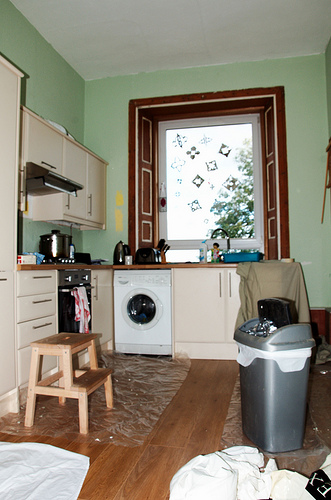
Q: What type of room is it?
A: It is a kitchen.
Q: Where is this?
A: This is at the kitchen.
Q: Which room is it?
A: It is a kitchen.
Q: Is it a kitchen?
A: Yes, it is a kitchen.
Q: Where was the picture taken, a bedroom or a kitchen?
A: It was taken at a kitchen.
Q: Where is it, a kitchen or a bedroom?
A: It is a kitchen.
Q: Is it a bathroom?
A: No, it is a kitchen.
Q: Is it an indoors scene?
A: Yes, it is indoors.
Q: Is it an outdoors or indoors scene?
A: It is indoors.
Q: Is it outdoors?
A: No, it is indoors.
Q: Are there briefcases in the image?
A: No, there are no briefcases.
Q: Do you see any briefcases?
A: No, there are no briefcases.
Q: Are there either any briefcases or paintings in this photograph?
A: No, there are no briefcases or paintings.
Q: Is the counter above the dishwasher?
A: Yes, the counter is above the dishwasher.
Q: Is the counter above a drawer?
A: No, the counter is above the dishwasher.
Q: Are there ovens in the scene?
A: Yes, there is an oven.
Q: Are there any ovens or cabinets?
A: Yes, there is an oven.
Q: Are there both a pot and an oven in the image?
A: Yes, there are both an oven and a pot.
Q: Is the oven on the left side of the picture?
A: Yes, the oven is on the left of the image.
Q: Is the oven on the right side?
A: No, the oven is on the left of the image.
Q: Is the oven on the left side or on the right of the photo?
A: The oven is on the left of the image.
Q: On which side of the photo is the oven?
A: The oven is on the left of the image.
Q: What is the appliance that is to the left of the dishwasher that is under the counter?
A: The appliance is an oven.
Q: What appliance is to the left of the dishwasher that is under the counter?
A: The appliance is an oven.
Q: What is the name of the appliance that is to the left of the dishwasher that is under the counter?
A: The appliance is an oven.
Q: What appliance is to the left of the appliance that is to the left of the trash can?
A: The appliance is an oven.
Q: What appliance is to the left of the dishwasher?
A: The appliance is an oven.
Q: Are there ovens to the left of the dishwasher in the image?
A: Yes, there is an oven to the left of the dishwasher.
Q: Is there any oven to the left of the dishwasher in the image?
A: Yes, there is an oven to the left of the dishwasher.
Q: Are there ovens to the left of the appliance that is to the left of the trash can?
A: Yes, there is an oven to the left of the dishwasher.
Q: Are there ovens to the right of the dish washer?
A: No, the oven is to the left of the dish washer.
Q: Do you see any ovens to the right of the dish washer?
A: No, the oven is to the left of the dish washer.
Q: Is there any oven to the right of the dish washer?
A: No, the oven is to the left of the dish washer.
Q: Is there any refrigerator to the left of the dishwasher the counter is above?
A: No, there is an oven to the left of the dish washer.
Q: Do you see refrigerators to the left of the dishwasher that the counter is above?
A: No, there is an oven to the left of the dish washer.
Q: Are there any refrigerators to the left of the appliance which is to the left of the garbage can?
A: No, there is an oven to the left of the dish washer.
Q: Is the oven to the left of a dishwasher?
A: Yes, the oven is to the left of a dishwasher.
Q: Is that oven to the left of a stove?
A: No, the oven is to the left of a dishwasher.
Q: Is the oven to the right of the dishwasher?
A: No, the oven is to the left of the dishwasher.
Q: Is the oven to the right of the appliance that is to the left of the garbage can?
A: No, the oven is to the left of the dishwasher.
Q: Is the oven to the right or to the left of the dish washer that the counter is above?
A: The oven is to the left of the dishwasher.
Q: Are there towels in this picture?
A: Yes, there is a towel.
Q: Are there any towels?
A: Yes, there is a towel.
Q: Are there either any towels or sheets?
A: Yes, there is a towel.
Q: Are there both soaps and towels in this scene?
A: No, there is a towel but no soaps.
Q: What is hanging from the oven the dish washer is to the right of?
A: The towel is hanging from the oven.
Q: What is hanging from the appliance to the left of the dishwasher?
A: The towel is hanging from the oven.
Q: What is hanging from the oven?
A: The towel is hanging from the oven.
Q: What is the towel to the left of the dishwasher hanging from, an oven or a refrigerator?
A: The towel is hanging from an oven.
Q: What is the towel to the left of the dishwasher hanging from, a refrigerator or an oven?
A: The towel is hanging from an oven.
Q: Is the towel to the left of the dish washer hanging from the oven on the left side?
A: Yes, the towel is hanging from the oven.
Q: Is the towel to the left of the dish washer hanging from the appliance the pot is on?
A: Yes, the towel is hanging from the oven.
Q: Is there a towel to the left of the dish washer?
A: Yes, there is a towel to the left of the dish washer.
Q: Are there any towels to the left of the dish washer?
A: Yes, there is a towel to the left of the dish washer.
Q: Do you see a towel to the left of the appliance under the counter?
A: Yes, there is a towel to the left of the dish washer.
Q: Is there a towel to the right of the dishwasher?
A: No, the towel is to the left of the dishwasher.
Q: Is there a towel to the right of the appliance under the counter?
A: No, the towel is to the left of the dishwasher.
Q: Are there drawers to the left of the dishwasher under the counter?
A: No, there is a towel to the left of the dish washer.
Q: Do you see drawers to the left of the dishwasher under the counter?
A: No, there is a towel to the left of the dish washer.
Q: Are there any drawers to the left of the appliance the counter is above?
A: No, there is a towel to the left of the dish washer.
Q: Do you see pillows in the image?
A: No, there are no pillows.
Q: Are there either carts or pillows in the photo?
A: No, there are no pillows or carts.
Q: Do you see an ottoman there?
A: No, there are no ottomen.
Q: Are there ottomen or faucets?
A: No, there are no ottomen or faucets.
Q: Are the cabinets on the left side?
A: Yes, the cabinets are on the left of the image.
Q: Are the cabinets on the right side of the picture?
A: No, the cabinets are on the left of the image.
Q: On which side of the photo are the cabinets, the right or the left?
A: The cabinets are on the left of the image.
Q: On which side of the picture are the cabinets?
A: The cabinets are on the left of the image.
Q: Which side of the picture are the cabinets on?
A: The cabinets are on the left of the image.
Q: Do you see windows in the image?
A: Yes, there is a window.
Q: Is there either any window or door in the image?
A: Yes, there is a window.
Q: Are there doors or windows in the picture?
A: Yes, there is a window.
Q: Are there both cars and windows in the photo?
A: No, there is a window but no cars.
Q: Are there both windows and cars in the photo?
A: No, there is a window but no cars.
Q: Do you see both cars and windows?
A: No, there is a window but no cars.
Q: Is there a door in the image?
A: No, there are no doors.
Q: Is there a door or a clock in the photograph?
A: No, there are no doors or clocks.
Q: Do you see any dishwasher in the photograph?
A: Yes, there is a dishwasher.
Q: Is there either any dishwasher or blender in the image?
A: Yes, there is a dishwasher.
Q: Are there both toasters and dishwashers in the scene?
A: Yes, there are both a dishwasher and a toaster.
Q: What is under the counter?
A: The dishwasher is under the counter.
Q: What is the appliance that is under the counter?
A: The appliance is a dishwasher.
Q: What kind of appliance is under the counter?
A: The appliance is a dishwasher.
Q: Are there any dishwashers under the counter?
A: Yes, there is a dishwasher under the counter.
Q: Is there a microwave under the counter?
A: No, there is a dishwasher under the counter.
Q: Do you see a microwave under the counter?
A: No, there is a dishwasher under the counter.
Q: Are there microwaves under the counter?
A: No, there is a dishwasher under the counter.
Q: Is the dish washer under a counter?
A: Yes, the dish washer is under a counter.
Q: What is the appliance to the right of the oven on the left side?
A: The appliance is a dishwasher.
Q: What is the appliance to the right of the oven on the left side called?
A: The appliance is a dishwasher.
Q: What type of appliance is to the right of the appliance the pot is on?
A: The appliance is a dishwasher.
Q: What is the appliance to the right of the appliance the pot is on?
A: The appliance is a dishwasher.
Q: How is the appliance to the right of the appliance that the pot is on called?
A: The appliance is a dishwasher.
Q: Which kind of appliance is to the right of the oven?
A: The appliance is a dishwasher.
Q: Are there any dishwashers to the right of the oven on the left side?
A: Yes, there is a dishwasher to the right of the oven.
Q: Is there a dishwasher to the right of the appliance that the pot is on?
A: Yes, there is a dishwasher to the right of the oven.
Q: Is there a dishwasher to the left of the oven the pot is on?
A: No, the dishwasher is to the right of the oven.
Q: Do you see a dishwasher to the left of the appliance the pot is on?
A: No, the dishwasher is to the right of the oven.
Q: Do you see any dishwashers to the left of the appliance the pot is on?
A: No, the dishwasher is to the right of the oven.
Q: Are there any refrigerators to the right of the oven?
A: No, there is a dishwasher to the right of the oven.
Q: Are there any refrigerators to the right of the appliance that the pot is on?
A: No, there is a dishwasher to the right of the oven.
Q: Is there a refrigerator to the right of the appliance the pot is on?
A: No, there is a dishwasher to the right of the oven.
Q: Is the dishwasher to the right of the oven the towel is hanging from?
A: Yes, the dishwasher is to the right of the oven.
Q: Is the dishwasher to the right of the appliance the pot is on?
A: Yes, the dishwasher is to the right of the oven.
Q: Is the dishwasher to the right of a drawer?
A: No, the dishwasher is to the right of the oven.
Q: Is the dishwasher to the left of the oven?
A: No, the dishwasher is to the right of the oven.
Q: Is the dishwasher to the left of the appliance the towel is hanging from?
A: No, the dishwasher is to the right of the oven.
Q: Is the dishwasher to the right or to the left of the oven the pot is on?
A: The dishwasher is to the right of the oven.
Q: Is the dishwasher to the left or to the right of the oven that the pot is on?
A: The dishwasher is to the right of the oven.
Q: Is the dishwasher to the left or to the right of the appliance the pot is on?
A: The dishwasher is to the right of the oven.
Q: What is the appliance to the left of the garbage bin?
A: The appliance is a dishwasher.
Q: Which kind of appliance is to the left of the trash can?
A: The appliance is a dishwasher.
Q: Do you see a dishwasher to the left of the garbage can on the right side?
A: Yes, there is a dishwasher to the left of the garbage bin.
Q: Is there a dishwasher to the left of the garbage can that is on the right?
A: Yes, there is a dishwasher to the left of the garbage bin.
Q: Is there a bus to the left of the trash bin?
A: No, there is a dishwasher to the left of the trash bin.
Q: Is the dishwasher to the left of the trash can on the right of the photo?
A: Yes, the dishwasher is to the left of the trashcan.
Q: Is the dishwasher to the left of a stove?
A: No, the dishwasher is to the left of the trashcan.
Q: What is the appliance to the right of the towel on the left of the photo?
A: The appliance is a dishwasher.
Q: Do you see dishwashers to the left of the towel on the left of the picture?
A: No, the dishwasher is to the right of the towel.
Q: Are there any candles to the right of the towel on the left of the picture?
A: No, there is a dishwasher to the right of the towel.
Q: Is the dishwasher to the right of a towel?
A: Yes, the dishwasher is to the right of a towel.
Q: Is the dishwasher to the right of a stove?
A: No, the dishwasher is to the right of a towel.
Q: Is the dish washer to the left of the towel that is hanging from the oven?
A: No, the dish washer is to the right of the towel.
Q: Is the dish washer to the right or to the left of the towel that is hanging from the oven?
A: The dish washer is to the right of the towel.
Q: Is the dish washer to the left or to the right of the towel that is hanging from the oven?
A: The dish washer is to the right of the towel.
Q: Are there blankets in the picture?
A: Yes, there is a blanket.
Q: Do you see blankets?
A: Yes, there is a blanket.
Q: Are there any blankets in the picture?
A: Yes, there is a blanket.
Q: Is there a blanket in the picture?
A: Yes, there is a blanket.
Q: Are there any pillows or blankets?
A: Yes, there is a blanket.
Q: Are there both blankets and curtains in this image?
A: No, there is a blanket but no curtains.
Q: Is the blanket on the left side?
A: Yes, the blanket is on the left of the image.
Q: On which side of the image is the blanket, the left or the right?
A: The blanket is on the left of the image.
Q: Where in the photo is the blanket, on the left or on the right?
A: The blanket is on the left of the image.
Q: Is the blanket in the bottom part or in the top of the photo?
A: The blanket is in the bottom of the image.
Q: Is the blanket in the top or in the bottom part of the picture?
A: The blanket is in the bottom of the image.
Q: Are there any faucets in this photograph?
A: No, there are no faucets.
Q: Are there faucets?
A: No, there are no faucets.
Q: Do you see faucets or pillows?
A: No, there are no faucets or pillows.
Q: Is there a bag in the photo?
A: Yes, there is a bag.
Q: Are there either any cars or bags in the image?
A: Yes, there is a bag.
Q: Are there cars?
A: No, there are no cars.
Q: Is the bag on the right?
A: Yes, the bag is on the right of the image.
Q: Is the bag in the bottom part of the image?
A: Yes, the bag is in the bottom of the image.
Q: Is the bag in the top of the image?
A: No, the bag is in the bottom of the image.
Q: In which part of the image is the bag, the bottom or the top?
A: The bag is in the bottom of the image.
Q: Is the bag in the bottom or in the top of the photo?
A: The bag is in the bottom of the image.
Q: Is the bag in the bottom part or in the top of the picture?
A: The bag is in the bottom of the image.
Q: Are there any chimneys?
A: No, there are no chimneys.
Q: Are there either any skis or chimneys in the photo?
A: No, there are no chimneys or skis.